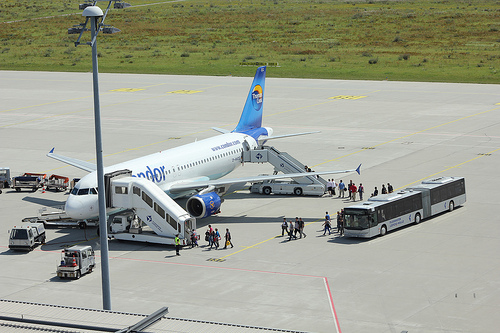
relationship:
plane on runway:
[61, 60, 307, 247] [5, 69, 499, 332]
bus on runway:
[339, 172, 472, 250] [5, 69, 499, 332]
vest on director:
[170, 237, 182, 247] [167, 229, 188, 258]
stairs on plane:
[134, 172, 194, 243] [55, 50, 285, 240]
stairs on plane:
[246, 131, 334, 191] [60, 37, 319, 256]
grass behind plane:
[2, 0, 496, 86] [52, 72, 329, 276]